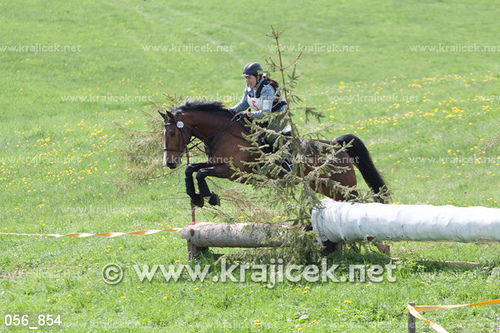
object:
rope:
[0, 228, 182, 238]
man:
[231, 62, 294, 176]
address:
[133, 258, 397, 289]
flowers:
[5, 58, 173, 209]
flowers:
[307, 81, 498, 162]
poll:
[182, 221, 344, 263]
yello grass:
[354, 75, 473, 134]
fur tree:
[229, 24, 395, 263]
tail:
[335, 133, 402, 204]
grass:
[0, 27, 499, 332]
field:
[0, 0, 499, 333]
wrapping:
[311, 198, 500, 245]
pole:
[181, 198, 500, 260]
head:
[157, 109, 192, 169]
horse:
[157, 97, 398, 254]